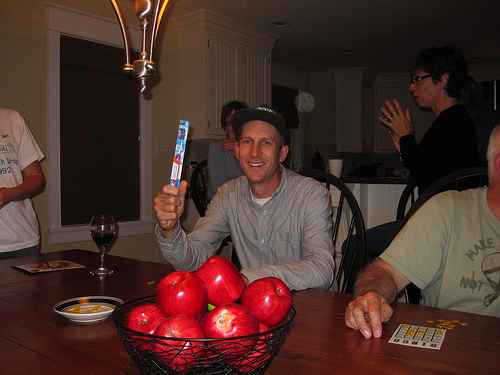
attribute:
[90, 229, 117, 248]
wine — red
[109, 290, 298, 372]
bowl — black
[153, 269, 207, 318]
apple — red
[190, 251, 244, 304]
apple — red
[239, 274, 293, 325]
apple — red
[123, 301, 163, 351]
apple — red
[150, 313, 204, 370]
apple — red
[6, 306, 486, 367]
table — brown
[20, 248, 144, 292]
table — brown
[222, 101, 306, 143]
hat — black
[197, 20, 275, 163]
cabinet — white